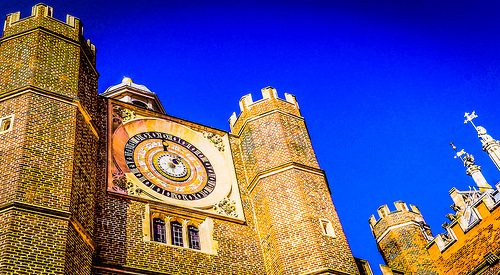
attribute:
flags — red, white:
[212, 76, 299, 136]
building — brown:
[1, 7, 498, 274]